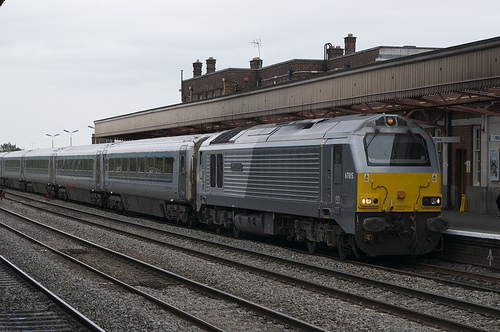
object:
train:
[146, 132, 449, 241]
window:
[361, 129, 435, 172]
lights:
[355, 194, 444, 210]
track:
[291, 254, 424, 308]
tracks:
[131, 243, 283, 324]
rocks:
[249, 241, 291, 258]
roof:
[206, 65, 253, 96]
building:
[90, 35, 497, 138]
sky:
[64, 18, 203, 67]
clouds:
[28, 29, 144, 93]